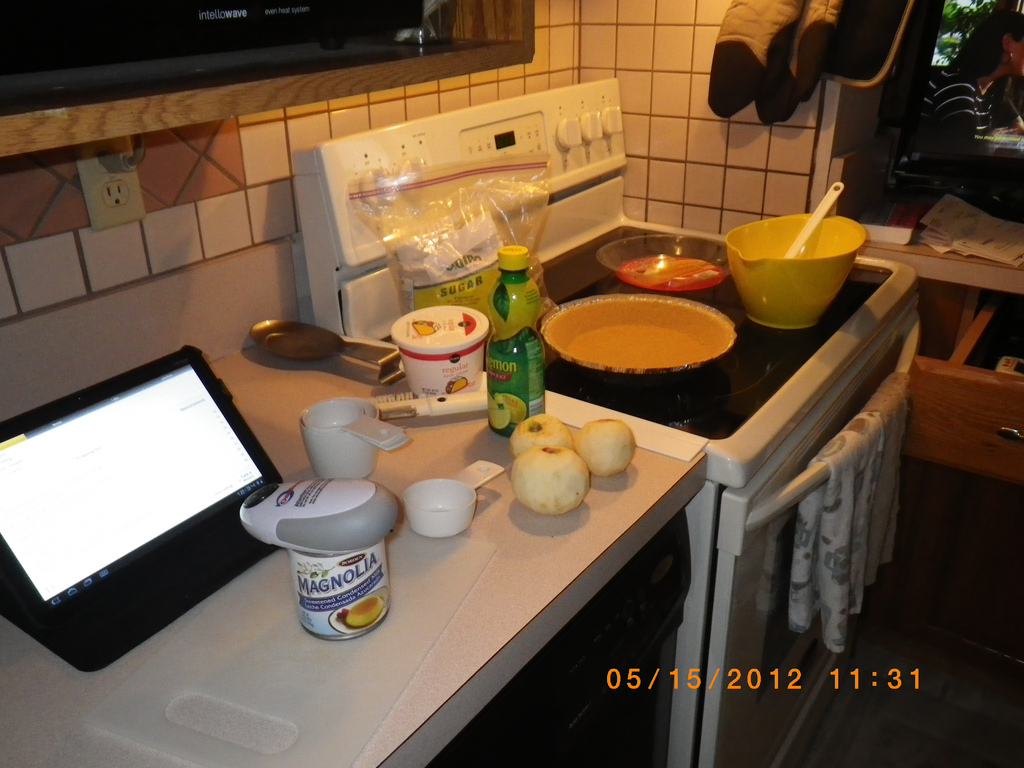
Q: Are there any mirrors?
A: No, there are no mirrors.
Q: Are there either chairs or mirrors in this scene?
A: No, there are no mirrors or chairs.